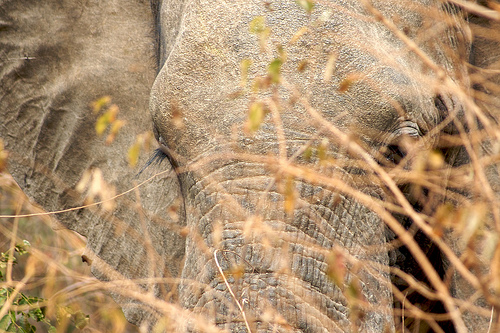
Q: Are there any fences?
A: No, there are no fences.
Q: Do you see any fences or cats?
A: No, there are no fences or cats.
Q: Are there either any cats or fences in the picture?
A: No, there are no fences or cats.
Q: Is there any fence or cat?
A: No, there are no fences or cats.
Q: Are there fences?
A: No, there are no fences.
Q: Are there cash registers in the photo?
A: No, there are no cash registers.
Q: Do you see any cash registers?
A: No, there are no cash registers.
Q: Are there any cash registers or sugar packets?
A: No, there are no cash registers or sugar packets.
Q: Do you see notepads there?
A: No, there are no notepads.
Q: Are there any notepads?
A: No, there are no notepads.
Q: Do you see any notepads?
A: No, there are no notepads.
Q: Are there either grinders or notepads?
A: No, there are no notepads or grinders.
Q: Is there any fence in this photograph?
A: No, there are no fences.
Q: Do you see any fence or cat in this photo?
A: No, there are no fences or cats.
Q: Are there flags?
A: No, there are no flags.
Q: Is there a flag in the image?
A: No, there are no flags.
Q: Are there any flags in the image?
A: No, there are no flags.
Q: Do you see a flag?
A: No, there are no flags.